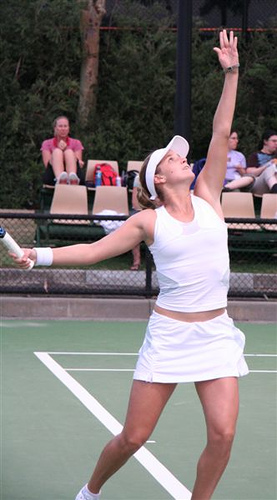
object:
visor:
[131, 135, 197, 197]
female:
[40, 115, 84, 184]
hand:
[212, 28, 239, 69]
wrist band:
[33, 246, 53, 268]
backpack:
[92, 161, 121, 187]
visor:
[142, 134, 191, 202]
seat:
[92, 184, 132, 226]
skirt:
[141, 311, 243, 383]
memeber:
[40, 115, 85, 185]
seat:
[259, 194, 276, 230]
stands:
[33, 158, 275, 255]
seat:
[53, 184, 90, 222]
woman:
[225, 131, 253, 191]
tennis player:
[6, 28, 249, 498]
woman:
[37, 114, 83, 185]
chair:
[68, 169, 115, 210]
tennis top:
[146, 188, 235, 318]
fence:
[1, 208, 275, 297]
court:
[1, 314, 276, 497]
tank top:
[147, 193, 231, 310]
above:
[154, 309, 225, 310]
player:
[17, 28, 247, 497]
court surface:
[13, 319, 119, 387]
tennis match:
[3, 23, 270, 498]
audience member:
[36, 115, 85, 182]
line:
[32, 342, 275, 358]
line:
[32, 343, 197, 498]